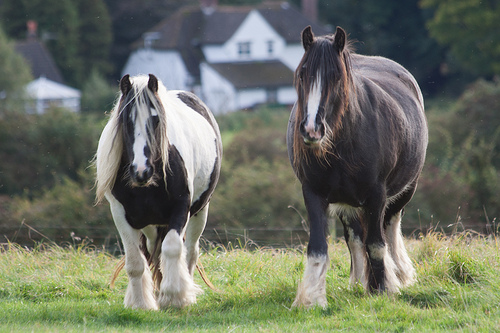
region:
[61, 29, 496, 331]
Two horses in the wild.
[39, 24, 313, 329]
Brown and white horse.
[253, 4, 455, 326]
Dark brown horse.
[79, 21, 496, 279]
Two horses on the field.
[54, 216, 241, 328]
Furry feet on the big horse.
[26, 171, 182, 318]
Grass on the ground.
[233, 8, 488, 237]
Mane on the horse.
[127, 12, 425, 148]
House in the background.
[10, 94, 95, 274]
Bushes in the background.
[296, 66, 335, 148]
White nose on the horse.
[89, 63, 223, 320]
White horse with brown patches walking on the grass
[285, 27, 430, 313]
Large brown horse with white accents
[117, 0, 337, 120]
Large white house with brown roof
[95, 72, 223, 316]
Brown and white horse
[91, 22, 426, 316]
Two horses walking together in the grass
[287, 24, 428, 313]
Horse with long hair in its eyes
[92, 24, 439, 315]
White and brown horse walking together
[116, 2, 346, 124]
Large two story house with fireplace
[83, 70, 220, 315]
Horse walking at a slow pace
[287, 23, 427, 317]
Brown horse with white stripe along its nose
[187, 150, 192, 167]
white fur on horse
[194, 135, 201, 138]
white fur on horse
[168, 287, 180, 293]
white fur on horse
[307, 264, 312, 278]
white fur on horse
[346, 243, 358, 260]
white fur on horse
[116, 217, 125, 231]
white fur on horse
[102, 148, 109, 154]
white fur on horse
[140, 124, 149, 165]
white fur on horse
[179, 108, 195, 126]
white fur on horse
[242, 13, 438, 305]
a black and white horse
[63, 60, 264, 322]
a white and black horse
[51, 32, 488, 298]
two black and white horses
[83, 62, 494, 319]
two white and black horses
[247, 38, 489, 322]
a black and white horse in a field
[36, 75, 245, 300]
a white and black horse in a field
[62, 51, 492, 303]
two horses in a field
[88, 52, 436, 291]
two black and white horses in a field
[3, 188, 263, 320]
field with a horse in it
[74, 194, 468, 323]
a field with two horses in it